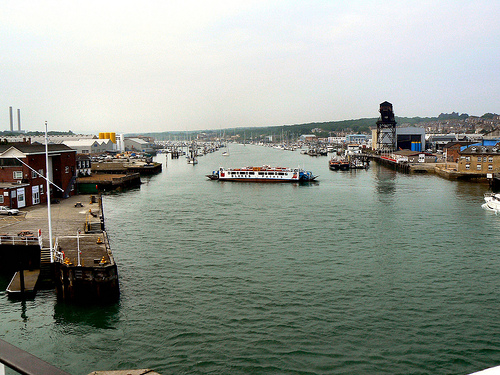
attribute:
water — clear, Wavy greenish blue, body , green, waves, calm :
[199, 233, 423, 358]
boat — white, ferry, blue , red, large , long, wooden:
[197, 145, 325, 204]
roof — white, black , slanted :
[61, 132, 127, 156]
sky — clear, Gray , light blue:
[148, 31, 349, 90]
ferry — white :
[215, 161, 336, 197]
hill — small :
[308, 109, 482, 132]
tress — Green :
[436, 114, 488, 137]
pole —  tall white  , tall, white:
[18, 119, 80, 266]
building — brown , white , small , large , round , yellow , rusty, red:
[2, 128, 102, 205]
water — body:
[14, 133, 484, 368]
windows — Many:
[228, 169, 292, 183]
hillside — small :
[264, 117, 434, 130]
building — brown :
[10, 147, 144, 207]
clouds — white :
[68, 22, 180, 55]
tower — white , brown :
[371, 99, 402, 172]